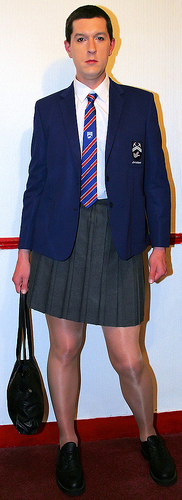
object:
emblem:
[131, 141, 143, 165]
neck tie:
[79, 91, 99, 210]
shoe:
[139, 430, 177, 486]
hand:
[11, 250, 30, 295]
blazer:
[17, 79, 171, 263]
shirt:
[73, 76, 109, 202]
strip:
[0, 232, 182, 249]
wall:
[0, 4, 182, 419]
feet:
[56, 438, 86, 496]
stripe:
[87, 94, 95, 101]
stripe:
[83, 105, 96, 121]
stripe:
[82, 136, 98, 157]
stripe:
[80, 181, 97, 202]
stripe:
[81, 170, 98, 191]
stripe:
[81, 159, 97, 181]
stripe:
[81, 147, 97, 169]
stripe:
[83, 115, 97, 133]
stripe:
[85, 102, 91, 109]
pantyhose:
[44, 313, 87, 448]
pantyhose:
[100, 325, 155, 437]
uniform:
[16, 74, 171, 328]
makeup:
[70, 18, 111, 79]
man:
[10, 1, 179, 500]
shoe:
[55, 430, 87, 500]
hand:
[148, 247, 169, 285]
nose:
[87, 37, 96, 53]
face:
[71, 17, 110, 79]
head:
[63, 3, 116, 79]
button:
[109, 201, 113, 208]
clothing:
[17, 76, 172, 264]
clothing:
[44, 314, 156, 447]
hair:
[64, 4, 114, 47]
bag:
[6, 290, 44, 436]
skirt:
[25, 199, 146, 329]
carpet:
[0, 438, 182, 499]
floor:
[0, 410, 182, 450]